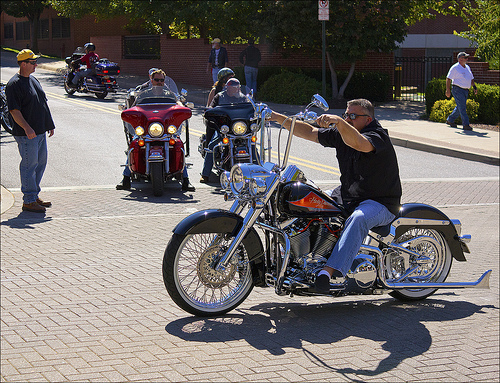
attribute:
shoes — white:
[306, 271, 333, 296]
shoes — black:
[297, 274, 338, 300]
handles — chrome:
[246, 87, 337, 189]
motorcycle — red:
[120, 95, 192, 202]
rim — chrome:
[176, 240, 245, 310]